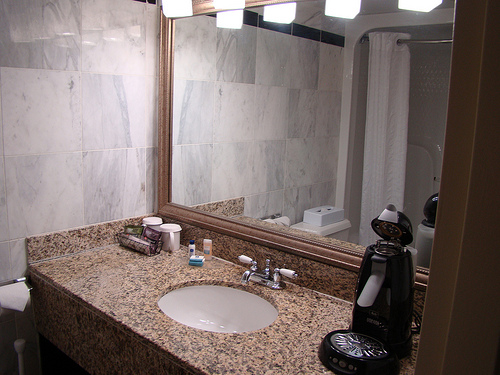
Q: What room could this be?
A: It is a bathroom.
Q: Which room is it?
A: It is a bathroom.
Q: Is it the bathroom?
A: Yes, it is the bathroom.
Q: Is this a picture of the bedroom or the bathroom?
A: It is showing the bathroom.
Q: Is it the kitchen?
A: No, it is the bathroom.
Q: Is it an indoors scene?
A: Yes, it is indoors.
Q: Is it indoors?
A: Yes, it is indoors.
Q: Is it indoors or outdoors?
A: It is indoors.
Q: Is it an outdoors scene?
A: No, it is indoors.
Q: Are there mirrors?
A: Yes, there is a mirror.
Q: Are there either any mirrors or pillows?
A: Yes, there is a mirror.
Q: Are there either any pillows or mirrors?
A: Yes, there is a mirror.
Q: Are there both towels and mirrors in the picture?
A: No, there is a mirror but no towels.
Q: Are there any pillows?
A: No, there are no pillows.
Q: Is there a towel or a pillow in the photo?
A: No, there are no pillows or towels.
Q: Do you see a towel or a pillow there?
A: No, there are no pillows or towels.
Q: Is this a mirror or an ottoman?
A: This is a mirror.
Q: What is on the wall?
A: The mirror is on the wall.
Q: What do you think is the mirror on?
A: The mirror is on the wall.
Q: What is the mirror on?
A: The mirror is on the wall.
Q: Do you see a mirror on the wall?
A: Yes, there is a mirror on the wall.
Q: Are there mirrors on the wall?
A: Yes, there is a mirror on the wall.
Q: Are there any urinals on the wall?
A: No, there is a mirror on the wall.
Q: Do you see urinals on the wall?
A: No, there is a mirror on the wall.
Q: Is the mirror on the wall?
A: Yes, the mirror is on the wall.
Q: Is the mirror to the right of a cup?
A: Yes, the mirror is to the right of a cup.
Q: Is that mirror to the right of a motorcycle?
A: No, the mirror is to the right of a cup.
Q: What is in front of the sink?
A: The mirror is in front of the sink.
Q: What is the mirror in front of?
A: The mirror is in front of the sink.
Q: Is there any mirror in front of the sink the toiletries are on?
A: Yes, there is a mirror in front of the sink.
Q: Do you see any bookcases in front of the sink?
A: No, there is a mirror in front of the sink.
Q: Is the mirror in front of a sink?
A: Yes, the mirror is in front of a sink.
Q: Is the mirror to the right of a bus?
A: No, the mirror is to the right of a cup.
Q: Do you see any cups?
A: Yes, there is a cup.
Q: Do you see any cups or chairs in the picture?
A: Yes, there is a cup.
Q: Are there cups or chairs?
A: Yes, there is a cup.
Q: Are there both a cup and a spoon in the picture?
A: No, there is a cup but no spoons.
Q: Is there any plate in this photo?
A: No, there are no plates.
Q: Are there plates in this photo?
A: No, there are no plates.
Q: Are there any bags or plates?
A: No, there are no plates or bags.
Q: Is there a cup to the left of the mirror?
A: Yes, there is a cup to the left of the mirror.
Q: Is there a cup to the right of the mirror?
A: No, the cup is to the left of the mirror.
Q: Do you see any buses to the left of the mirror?
A: No, there is a cup to the left of the mirror.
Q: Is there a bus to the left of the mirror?
A: No, there is a cup to the left of the mirror.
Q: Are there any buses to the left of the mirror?
A: No, there is a cup to the left of the mirror.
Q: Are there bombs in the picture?
A: No, there are no bombs.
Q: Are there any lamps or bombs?
A: No, there are no bombs or lamps.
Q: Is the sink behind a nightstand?
A: No, the sink is behind a mirror.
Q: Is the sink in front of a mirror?
A: No, the sink is behind a mirror.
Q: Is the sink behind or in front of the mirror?
A: The sink is behind the mirror.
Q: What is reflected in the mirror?
A: The shower is reflected in the mirror.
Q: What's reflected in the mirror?
A: The shower is reflected in the mirror.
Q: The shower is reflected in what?
A: The shower is reflected in the mirror.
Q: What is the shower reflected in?
A: The shower is reflected in the mirror.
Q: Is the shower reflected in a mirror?
A: Yes, the shower is reflected in a mirror.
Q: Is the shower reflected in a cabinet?
A: No, the shower is reflected in a mirror.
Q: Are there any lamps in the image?
A: No, there are no lamps.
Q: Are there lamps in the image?
A: No, there are no lamps.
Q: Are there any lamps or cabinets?
A: No, there are no lamps or cabinets.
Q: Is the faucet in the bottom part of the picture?
A: Yes, the faucet is in the bottom of the image.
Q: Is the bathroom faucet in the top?
A: No, the faucet is in the bottom of the image.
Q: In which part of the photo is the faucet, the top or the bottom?
A: The faucet is in the bottom of the image.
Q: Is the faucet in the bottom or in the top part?
A: The faucet is in the bottom of the image.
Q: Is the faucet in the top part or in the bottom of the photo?
A: The faucet is in the bottom of the image.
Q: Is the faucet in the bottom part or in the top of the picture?
A: The faucet is in the bottom of the image.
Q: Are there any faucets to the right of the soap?
A: Yes, there is a faucet to the right of the soap.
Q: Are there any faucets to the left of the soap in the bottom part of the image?
A: No, the faucet is to the right of the soap.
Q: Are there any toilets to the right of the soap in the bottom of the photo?
A: No, there is a faucet to the right of the soap.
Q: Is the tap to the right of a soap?
A: Yes, the tap is to the right of a soap.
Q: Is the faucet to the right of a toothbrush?
A: No, the faucet is to the right of a soap.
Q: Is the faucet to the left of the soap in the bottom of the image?
A: No, the faucet is to the right of the soap.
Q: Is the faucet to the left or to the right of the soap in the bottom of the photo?
A: The faucet is to the right of the soap.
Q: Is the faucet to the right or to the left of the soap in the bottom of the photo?
A: The faucet is to the right of the soap.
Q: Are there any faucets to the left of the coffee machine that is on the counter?
A: Yes, there is a faucet to the left of the coffee machine.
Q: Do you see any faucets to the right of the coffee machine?
A: No, the faucet is to the left of the coffee machine.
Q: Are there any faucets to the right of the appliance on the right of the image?
A: No, the faucet is to the left of the coffee machine.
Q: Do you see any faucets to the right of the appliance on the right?
A: No, the faucet is to the left of the coffee machine.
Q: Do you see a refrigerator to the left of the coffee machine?
A: No, there is a faucet to the left of the coffee machine.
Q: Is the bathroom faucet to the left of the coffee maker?
A: Yes, the tap is to the left of the coffee maker.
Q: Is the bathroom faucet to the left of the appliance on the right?
A: Yes, the tap is to the left of the coffee maker.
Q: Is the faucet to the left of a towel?
A: No, the faucet is to the left of the coffee maker.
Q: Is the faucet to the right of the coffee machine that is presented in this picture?
A: No, the faucet is to the left of the coffee machine.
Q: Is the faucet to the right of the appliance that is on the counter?
A: No, the faucet is to the left of the coffee machine.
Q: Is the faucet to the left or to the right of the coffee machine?
A: The faucet is to the left of the coffee machine.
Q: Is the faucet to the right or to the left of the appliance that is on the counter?
A: The faucet is to the left of the coffee machine.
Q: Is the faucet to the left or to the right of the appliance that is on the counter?
A: The faucet is to the left of the coffee machine.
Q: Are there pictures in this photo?
A: No, there are no pictures.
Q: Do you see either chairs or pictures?
A: No, there are no pictures or chairs.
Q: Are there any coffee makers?
A: Yes, there is a coffee maker.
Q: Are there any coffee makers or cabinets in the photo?
A: Yes, there is a coffee maker.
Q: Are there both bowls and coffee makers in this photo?
A: No, there is a coffee maker but no bowls.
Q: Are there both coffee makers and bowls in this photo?
A: No, there is a coffee maker but no bowls.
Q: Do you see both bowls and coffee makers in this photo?
A: No, there is a coffee maker but no bowls.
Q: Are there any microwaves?
A: No, there are no microwaves.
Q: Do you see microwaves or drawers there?
A: No, there are no microwaves or drawers.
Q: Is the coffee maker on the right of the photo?
A: Yes, the coffee maker is on the right of the image.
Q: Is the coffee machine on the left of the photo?
A: No, the coffee machine is on the right of the image.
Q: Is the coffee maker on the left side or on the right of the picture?
A: The coffee maker is on the right of the image.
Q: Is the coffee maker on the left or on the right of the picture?
A: The coffee maker is on the right of the image.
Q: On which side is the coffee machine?
A: The coffee machine is on the right of the image.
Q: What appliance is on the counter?
A: The appliance is a coffee maker.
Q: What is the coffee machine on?
A: The coffee machine is on the counter.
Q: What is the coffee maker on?
A: The coffee machine is on the counter.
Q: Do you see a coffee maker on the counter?
A: Yes, there is a coffee maker on the counter.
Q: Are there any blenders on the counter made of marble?
A: No, there is a coffee maker on the counter.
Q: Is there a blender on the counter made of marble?
A: No, there is a coffee maker on the counter.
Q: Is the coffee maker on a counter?
A: Yes, the coffee maker is on a counter.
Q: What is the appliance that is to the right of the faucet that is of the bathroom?
A: The appliance is a coffee maker.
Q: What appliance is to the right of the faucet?
A: The appliance is a coffee maker.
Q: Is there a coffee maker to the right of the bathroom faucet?
A: Yes, there is a coffee maker to the right of the faucet.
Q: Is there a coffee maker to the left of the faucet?
A: No, the coffee maker is to the right of the faucet.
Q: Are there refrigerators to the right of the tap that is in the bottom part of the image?
A: No, there is a coffee maker to the right of the tap.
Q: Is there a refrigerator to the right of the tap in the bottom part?
A: No, there is a coffee maker to the right of the tap.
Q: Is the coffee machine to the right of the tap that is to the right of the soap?
A: Yes, the coffee machine is to the right of the tap.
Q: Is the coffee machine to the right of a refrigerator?
A: No, the coffee machine is to the right of the tap.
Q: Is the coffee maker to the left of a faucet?
A: No, the coffee maker is to the right of a faucet.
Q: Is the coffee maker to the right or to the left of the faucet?
A: The coffee maker is to the right of the faucet.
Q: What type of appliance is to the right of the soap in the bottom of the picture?
A: The appliance is a coffee maker.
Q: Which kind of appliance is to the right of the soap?
A: The appliance is a coffee maker.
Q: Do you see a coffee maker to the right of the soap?
A: Yes, there is a coffee maker to the right of the soap.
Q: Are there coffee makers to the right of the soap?
A: Yes, there is a coffee maker to the right of the soap.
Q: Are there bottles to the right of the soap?
A: No, there is a coffee maker to the right of the soap.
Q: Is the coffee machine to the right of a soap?
A: Yes, the coffee machine is to the right of a soap.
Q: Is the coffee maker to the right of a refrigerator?
A: No, the coffee maker is to the right of a soap.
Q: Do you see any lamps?
A: No, there are no lamps.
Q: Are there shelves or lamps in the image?
A: No, there are no lamps or shelves.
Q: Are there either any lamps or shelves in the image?
A: No, there are no lamps or shelves.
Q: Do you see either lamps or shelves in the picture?
A: No, there are no lamps or shelves.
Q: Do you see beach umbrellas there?
A: No, there are no beach umbrellas.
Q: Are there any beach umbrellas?
A: No, there are no beach umbrellas.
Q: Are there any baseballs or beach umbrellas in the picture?
A: No, there are no beach umbrellas or baseballs.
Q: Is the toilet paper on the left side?
A: Yes, the toilet paper is on the left of the image.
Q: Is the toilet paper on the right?
A: No, the toilet paper is on the left of the image.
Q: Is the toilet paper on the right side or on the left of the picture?
A: The toilet paper is on the left of the image.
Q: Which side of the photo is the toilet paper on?
A: The toilet paper is on the left of the image.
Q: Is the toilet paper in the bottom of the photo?
A: Yes, the toilet paper is in the bottom of the image.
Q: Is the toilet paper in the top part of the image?
A: No, the toilet paper is in the bottom of the image.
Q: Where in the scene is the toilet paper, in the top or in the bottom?
A: The toilet paper is in the bottom of the image.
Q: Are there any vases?
A: No, there are no vases.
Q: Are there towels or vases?
A: No, there are no vases or towels.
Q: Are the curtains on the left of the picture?
A: No, the curtains are on the right of the image.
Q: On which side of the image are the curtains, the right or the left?
A: The curtains are on the right of the image.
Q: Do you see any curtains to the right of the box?
A: Yes, there are curtains to the right of the box.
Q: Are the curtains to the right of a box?
A: Yes, the curtains are to the right of a box.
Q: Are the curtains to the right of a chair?
A: No, the curtains are to the right of a box.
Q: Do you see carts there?
A: No, there are no carts.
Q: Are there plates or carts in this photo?
A: No, there are no carts or plates.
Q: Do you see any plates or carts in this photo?
A: No, there are no carts or plates.